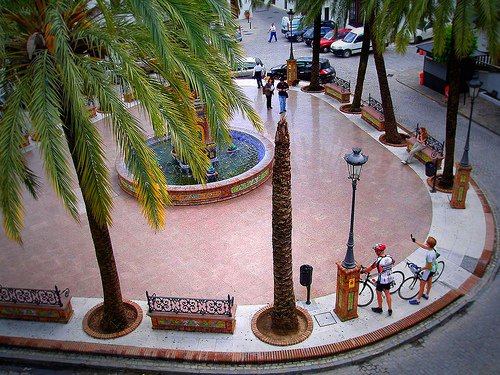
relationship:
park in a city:
[12, 52, 495, 344] [8, 53, 490, 368]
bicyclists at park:
[358, 232, 446, 316] [359, 231, 448, 317]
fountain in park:
[115, 62, 278, 207] [115, 88, 274, 206]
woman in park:
[402, 123, 434, 169] [399, 124, 436, 166]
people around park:
[249, 57, 294, 117] [248, 57, 294, 118]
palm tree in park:
[7, 4, 263, 338] [4, 3, 271, 368]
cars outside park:
[275, 10, 392, 59] [281, 10, 390, 59]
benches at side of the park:
[2, 282, 243, 335] [3, 282, 240, 338]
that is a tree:
[427, 1, 495, 197] [424, 2, 492, 196]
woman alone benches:
[398, 122, 445, 168] [404, 123, 443, 169]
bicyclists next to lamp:
[358, 242, 395, 318] [332, 145, 393, 322]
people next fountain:
[165, 68, 292, 205] [115, 62, 278, 207]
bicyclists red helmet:
[358, 242, 395, 318] [370, 241, 388, 259]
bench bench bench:
[144, 290, 236, 335] [144, 290, 236, 335]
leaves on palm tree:
[3, 1, 267, 248] [3, 3, 271, 247]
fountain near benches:
[115, 82, 273, 205] [114, 98, 275, 207]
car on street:
[266, 56, 339, 87] [267, 55, 339, 87]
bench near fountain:
[144, 285, 239, 337] [144, 287, 240, 338]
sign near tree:
[341, 275, 361, 293] [344, 274, 359, 292]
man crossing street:
[265, 19, 281, 46] [265, 20, 280, 45]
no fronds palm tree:
[259, 107, 311, 337] [259, 107, 310, 335]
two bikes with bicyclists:
[353, 232, 447, 317] [354, 228, 449, 317]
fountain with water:
[115, 62, 278, 207] [116, 97, 275, 209]